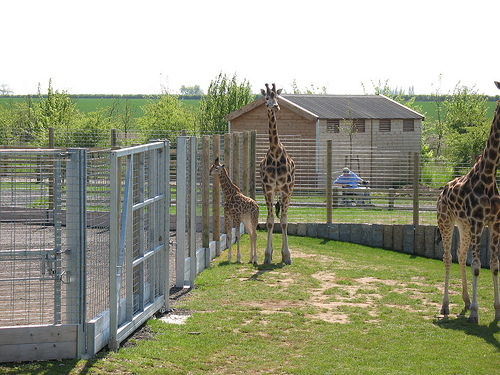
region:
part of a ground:
[271, 329, 288, 349]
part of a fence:
[369, 171, 406, 208]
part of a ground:
[298, 263, 343, 350]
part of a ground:
[323, 272, 339, 296]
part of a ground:
[321, 297, 336, 323]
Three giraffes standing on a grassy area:
[135, 73, 497, 358]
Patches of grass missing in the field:
[146, 222, 464, 330]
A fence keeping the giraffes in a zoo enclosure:
[0, 97, 492, 273]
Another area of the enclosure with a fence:
[0, 85, 285, 356]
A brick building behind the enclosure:
[210, 67, 436, 202]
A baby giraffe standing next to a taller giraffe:
[198, 72, 338, 267]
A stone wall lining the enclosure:
[210, 216, 495, 267]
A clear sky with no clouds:
[1, 0, 482, 85]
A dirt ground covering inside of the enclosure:
[2, 127, 249, 324]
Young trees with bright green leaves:
[0, 60, 484, 191]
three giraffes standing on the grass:
[198, 79, 499, 359]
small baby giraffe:
[198, 150, 276, 267]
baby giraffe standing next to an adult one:
[200, 79, 312, 274]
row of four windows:
[319, 118, 421, 137]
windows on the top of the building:
[323, 115, 420, 138]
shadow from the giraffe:
[437, 311, 497, 365]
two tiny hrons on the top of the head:
[264, 81, 277, 93]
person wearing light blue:
[332, 161, 369, 199]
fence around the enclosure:
[0, 122, 497, 374]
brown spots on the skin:
[426, 114, 498, 281]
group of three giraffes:
[200, 73, 499, 333]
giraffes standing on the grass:
[198, 78, 498, 341]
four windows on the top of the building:
[324, 117, 419, 137]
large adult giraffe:
[254, 83, 309, 272]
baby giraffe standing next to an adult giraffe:
[203, 78, 320, 276]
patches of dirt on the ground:
[257, 252, 463, 346]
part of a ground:
[309, 280, 333, 320]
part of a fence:
[386, 181, 410, 215]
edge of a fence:
[62, 280, 96, 344]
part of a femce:
[326, 236, 329, 243]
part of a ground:
[321, 309, 338, 331]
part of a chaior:
[281, 325, 301, 355]